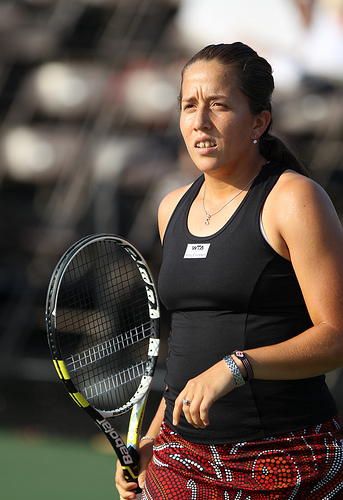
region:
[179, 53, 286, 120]
woman has brown hair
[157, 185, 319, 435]
woman has black shirt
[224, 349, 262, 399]
woman wears purple bracelet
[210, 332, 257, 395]
woman is wearing watch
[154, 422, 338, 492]
red and grey shorts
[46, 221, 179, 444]
yellow and black racket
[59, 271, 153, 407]
black and grey strings on racket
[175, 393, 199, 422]
woman is wearing ring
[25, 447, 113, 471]
green court behind woman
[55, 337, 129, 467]
yellow stripes on racket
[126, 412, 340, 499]
Woman is wearing a skirt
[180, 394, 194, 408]
Woman is wearing a ring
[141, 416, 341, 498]
Woman wearing a skirt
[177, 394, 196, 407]
Woman wearing a ring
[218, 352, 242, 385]
Woman wearing a bracelet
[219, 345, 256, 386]
Woman wearing bracelets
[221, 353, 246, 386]
Woman is wearing a bracelet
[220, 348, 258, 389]
Woman is wearing bracelets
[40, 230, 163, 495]
Woman holding a tennis racket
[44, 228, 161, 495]
Woman is holding a tennis racket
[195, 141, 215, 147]
teeth in a mouth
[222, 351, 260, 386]
two bracelets on a woman's wrist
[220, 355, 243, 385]
bracelet on a woman's wrist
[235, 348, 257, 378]
black and pink bracelet on a woman's wrist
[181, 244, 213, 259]
black and white label on a tank top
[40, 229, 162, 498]
black yellow and white tennis racket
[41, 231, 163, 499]
tennis racket in a woman's hand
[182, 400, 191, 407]
ring on a woman's finger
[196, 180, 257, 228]
silver necklace around a woman's neck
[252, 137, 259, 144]
earring on a woman's ear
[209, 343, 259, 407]
player is wearing bracelets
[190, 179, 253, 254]
the player is wearing necklace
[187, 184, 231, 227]
the player is wearing necklace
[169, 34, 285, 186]
Woman with black hair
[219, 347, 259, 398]
woman wearing a wrist watch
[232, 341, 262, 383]
woman with a pink band on her wrist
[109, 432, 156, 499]
woman holding a tennis racket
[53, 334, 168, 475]
yellow and black tennis racket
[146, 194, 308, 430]
woman wearing a black shirt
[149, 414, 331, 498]
woman wearing a plaid dress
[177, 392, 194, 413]
woman wearing a engagement ring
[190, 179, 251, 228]
woman wearing a necklace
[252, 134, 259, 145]
woman wearing earrings